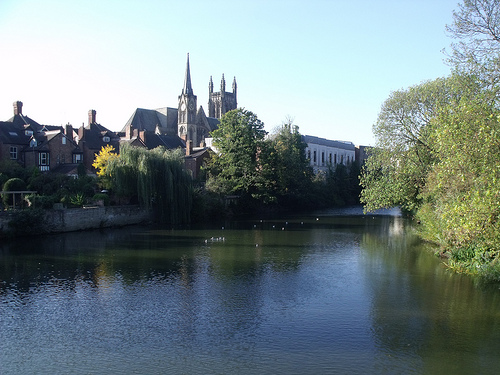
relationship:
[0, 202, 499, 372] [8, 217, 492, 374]
water is green re reflection reflection in water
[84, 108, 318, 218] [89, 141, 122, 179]
trees are in group. re are trees there is yellow tree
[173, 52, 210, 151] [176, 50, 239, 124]
building church has steeple steeple is grey.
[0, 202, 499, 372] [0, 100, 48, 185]
there is a lake. building large home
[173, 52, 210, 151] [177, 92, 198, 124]
building tower square tower has stripes.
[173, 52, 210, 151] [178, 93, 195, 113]
building re a clock clock is on tower.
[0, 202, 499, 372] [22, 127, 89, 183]
there is a river. re a house house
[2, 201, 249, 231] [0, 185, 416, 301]
there is a wall. wall along riverbank there is a riverbank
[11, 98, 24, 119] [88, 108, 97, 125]
there is a chimney. re a roof chimney is on roof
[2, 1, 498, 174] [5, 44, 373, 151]
sky is clear. clouds are little sky has clouds.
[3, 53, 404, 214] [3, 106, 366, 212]
there are buildings. trees are in group trees are in front.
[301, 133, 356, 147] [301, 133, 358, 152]
roof is grey. re white house roof is grey.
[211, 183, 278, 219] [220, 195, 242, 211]
there is a bridge. bridge on left there is a bridge.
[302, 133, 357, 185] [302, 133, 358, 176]
there is building. building white there is a building.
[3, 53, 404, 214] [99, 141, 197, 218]
there are buildings. re a lake tree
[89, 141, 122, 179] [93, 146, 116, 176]
leaves are yellow. re a tree tree has branch.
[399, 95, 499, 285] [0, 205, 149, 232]
trees growing on there is a riverbank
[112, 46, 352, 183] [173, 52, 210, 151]
building has building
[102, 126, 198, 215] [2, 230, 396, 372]
tree hanging over river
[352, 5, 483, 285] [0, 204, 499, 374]
trees on side of there is a lake.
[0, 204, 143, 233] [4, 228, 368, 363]
there is a wall. on side of river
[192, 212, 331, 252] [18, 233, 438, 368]
birds on water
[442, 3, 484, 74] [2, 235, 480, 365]
tree on side of river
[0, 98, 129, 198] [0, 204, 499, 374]
home overlooking there is a lake.